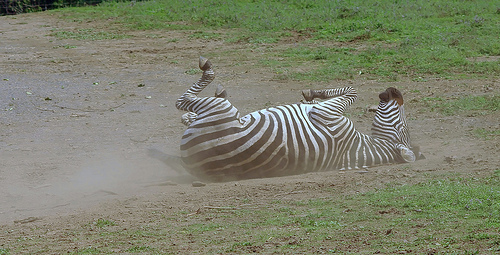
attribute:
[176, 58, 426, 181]
zebra — on land, animal, raising dust, black, white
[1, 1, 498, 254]
dirt — brown, dry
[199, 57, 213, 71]
hoof — black, gray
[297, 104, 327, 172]
stripe — black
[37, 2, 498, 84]
grass — growing, patchy, green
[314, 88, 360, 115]
leg — bent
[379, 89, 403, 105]
nose — black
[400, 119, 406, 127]
eye — closed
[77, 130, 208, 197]
dust — in air